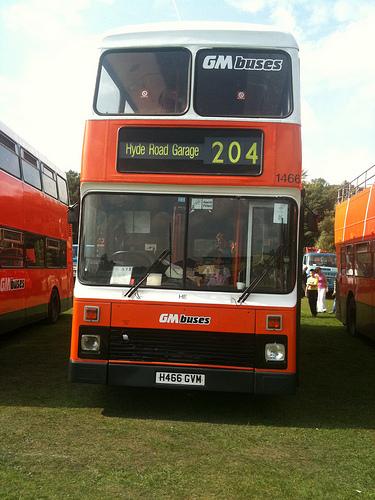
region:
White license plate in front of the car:
[152, 368, 205, 387]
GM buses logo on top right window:
[203, 51, 285, 74]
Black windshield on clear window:
[121, 242, 176, 299]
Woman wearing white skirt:
[314, 264, 330, 314]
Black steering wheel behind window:
[104, 246, 157, 281]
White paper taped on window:
[268, 201, 288, 227]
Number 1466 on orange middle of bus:
[275, 168, 301, 186]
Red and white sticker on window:
[138, 87, 149, 100]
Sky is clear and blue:
[0, 0, 374, 188]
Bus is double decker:
[65, 24, 308, 400]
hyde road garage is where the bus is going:
[118, 141, 208, 163]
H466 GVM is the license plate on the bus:
[155, 369, 211, 389]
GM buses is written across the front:
[157, 311, 215, 327]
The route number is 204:
[206, 134, 260, 174]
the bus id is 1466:
[274, 171, 304, 184]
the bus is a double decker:
[63, 29, 300, 376]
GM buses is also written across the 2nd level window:
[202, 55, 290, 78]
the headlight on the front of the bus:
[77, 334, 104, 352]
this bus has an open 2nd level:
[329, 165, 372, 250]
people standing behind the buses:
[306, 264, 330, 313]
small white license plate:
[153, 370, 204, 387]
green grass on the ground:
[71, 383, 289, 476]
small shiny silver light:
[254, 334, 302, 369]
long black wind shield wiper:
[207, 254, 291, 329]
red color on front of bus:
[72, 295, 321, 353]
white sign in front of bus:
[85, 248, 161, 308]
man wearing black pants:
[303, 282, 322, 316]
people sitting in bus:
[193, 215, 251, 294]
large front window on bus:
[64, 174, 314, 311]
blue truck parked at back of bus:
[307, 249, 352, 292]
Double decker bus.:
[70, 22, 314, 395]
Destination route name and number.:
[108, 122, 268, 182]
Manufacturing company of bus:
[155, 308, 216, 329]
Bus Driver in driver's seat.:
[201, 217, 240, 287]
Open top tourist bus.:
[334, 159, 373, 350]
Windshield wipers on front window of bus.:
[123, 240, 288, 303]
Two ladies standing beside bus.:
[306, 263, 327, 316]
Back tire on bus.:
[42, 278, 66, 328]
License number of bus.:
[150, 361, 218, 398]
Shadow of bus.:
[169, 307, 369, 493]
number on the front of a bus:
[245, 135, 259, 168]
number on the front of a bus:
[226, 136, 243, 164]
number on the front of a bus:
[206, 138, 227, 164]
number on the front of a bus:
[293, 171, 302, 186]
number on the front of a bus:
[286, 169, 295, 186]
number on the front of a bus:
[279, 169, 288, 184]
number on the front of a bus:
[274, 170, 282, 185]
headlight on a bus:
[260, 335, 288, 367]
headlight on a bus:
[75, 329, 102, 356]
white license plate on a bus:
[151, 369, 207, 383]